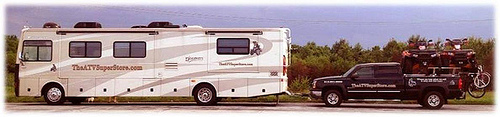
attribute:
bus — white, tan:
[18, 32, 283, 101]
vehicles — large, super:
[26, 24, 472, 104]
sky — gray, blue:
[224, 10, 487, 45]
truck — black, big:
[311, 68, 462, 105]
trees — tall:
[288, 44, 392, 74]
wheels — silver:
[47, 92, 232, 106]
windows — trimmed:
[55, 36, 161, 65]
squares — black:
[71, 79, 189, 93]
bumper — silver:
[59, 26, 160, 42]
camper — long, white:
[12, 11, 299, 68]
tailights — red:
[457, 77, 467, 93]